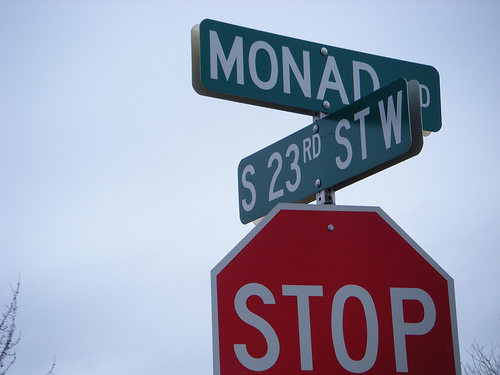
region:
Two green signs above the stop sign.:
[178, 20, 445, 202]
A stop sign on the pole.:
[185, 220, 467, 370]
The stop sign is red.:
[208, 250, 393, 372]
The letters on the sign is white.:
[233, 279, 436, 362]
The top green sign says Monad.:
[190, 12, 443, 117]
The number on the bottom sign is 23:
[252, 117, 315, 192]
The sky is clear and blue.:
[37, 63, 174, 215]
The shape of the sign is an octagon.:
[208, 203, 480, 373]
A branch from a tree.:
[3, 287, 25, 363]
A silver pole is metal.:
[302, 108, 354, 205]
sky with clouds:
[61, 49, 147, 329]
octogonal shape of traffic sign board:
[203, 213, 489, 373]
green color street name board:
[193, 18, 452, 200]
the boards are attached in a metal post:
[195, 14, 483, 374]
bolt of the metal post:
[315, 175, 322, 188]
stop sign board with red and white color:
[238, 270, 450, 370]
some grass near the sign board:
[470, 334, 496, 374]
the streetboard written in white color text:
[209, 27, 416, 167]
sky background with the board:
[114, 15, 465, 372]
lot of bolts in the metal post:
[287, 36, 356, 251]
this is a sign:
[206, 203, 487, 374]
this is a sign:
[232, 75, 422, 227]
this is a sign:
[189, 11, 457, 142]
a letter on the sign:
[205, 20, 250, 86]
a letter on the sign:
[232, 271, 280, 372]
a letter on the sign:
[269, 268, 331, 374]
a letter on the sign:
[322, 279, 389, 374]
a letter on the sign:
[381, 278, 442, 373]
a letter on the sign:
[241, 157, 262, 217]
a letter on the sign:
[373, 86, 410, 158]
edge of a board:
[205, 326, 232, 362]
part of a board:
[282, 230, 299, 263]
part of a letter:
[231, 275, 257, 345]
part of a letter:
[252, 295, 295, 372]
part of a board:
[253, 236, 293, 320]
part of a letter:
[245, 307, 260, 334]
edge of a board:
[214, 263, 236, 295]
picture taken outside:
[14, 31, 428, 372]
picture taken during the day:
[67, 37, 475, 292]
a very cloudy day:
[52, 58, 174, 340]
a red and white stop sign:
[182, 201, 496, 359]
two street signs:
[177, 24, 432, 188]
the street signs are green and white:
[198, 35, 445, 163]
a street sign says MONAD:
[210, 24, 345, 125]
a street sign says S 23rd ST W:
[204, 143, 428, 177]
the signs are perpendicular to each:
[180, 38, 495, 222]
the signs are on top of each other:
[178, 13, 370, 374]